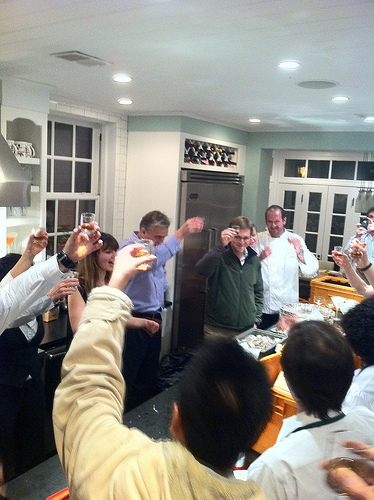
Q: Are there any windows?
A: Yes, there is a window.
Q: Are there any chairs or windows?
A: Yes, there is a window.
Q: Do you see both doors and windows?
A: Yes, there are both a window and a door.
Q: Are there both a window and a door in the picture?
A: Yes, there are both a window and a door.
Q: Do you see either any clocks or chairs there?
A: No, there are no chairs or clocks.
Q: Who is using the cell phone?
A: The man is using the cell phone.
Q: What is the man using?
A: The man is using a cell phone.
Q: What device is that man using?
A: The man is using a cellphone.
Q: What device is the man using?
A: The man is using a cellphone.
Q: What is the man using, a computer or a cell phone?
A: The man is using a cell phone.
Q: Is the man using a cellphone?
A: Yes, the man is using a cellphone.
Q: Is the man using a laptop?
A: No, the man is using a cellphone.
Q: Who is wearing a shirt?
A: The man is wearing a shirt.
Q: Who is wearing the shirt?
A: The man is wearing a shirt.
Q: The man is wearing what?
A: The man is wearing a shirt.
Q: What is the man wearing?
A: The man is wearing a shirt.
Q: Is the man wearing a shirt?
A: Yes, the man is wearing a shirt.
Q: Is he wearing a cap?
A: No, the man is wearing a shirt.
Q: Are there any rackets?
A: No, there are no rackets.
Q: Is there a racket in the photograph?
A: No, there are no rackets.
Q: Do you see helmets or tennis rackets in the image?
A: No, there are no tennis rackets or helmets.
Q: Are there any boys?
A: No, there are no boys.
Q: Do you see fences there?
A: No, there are no fences.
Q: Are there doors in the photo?
A: Yes, there is a door.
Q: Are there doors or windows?
A: Yes, there is a door.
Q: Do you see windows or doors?
A: Yes, there is a door.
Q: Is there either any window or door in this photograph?
A: Yes, there is a door.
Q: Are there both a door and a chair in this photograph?
A: No, there is a door but no chairs.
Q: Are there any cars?
A: No, there are no cars.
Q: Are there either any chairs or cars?
A: No, there are no cars or chairs.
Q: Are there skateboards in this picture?
A: No, there are no skateboards.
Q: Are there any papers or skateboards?
A: No, there are no skateboards or papers.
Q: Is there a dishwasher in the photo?
A: Yes, there is a dishwasher.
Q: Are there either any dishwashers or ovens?
A: Yes, there is a dishwasher.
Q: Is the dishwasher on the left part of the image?
A: Yes, the dishwasher is on the left of the image.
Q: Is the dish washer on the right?
A: No, the dish washer is on the left of the image.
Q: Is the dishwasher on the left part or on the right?
A: The dishwasher is on the left of the image.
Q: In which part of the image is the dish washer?
A: The dish washer is on the left of the image.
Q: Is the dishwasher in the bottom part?
A: Yes, the dishwasher is in the bottom of the image.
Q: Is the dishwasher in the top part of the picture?
A: No, the dishwasher is in the bottom of the image.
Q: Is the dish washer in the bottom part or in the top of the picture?
A: The dish washer is in the bottom of the image.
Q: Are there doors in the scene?
A: Yes, there is a door.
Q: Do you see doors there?
A: Yes, there is a door.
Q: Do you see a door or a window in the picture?
A: Yes, there is a door.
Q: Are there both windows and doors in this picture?
A: Yes, there are both a door and a window.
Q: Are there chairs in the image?
A: No, there are no chairs.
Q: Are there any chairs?
A: No, there are no chairs.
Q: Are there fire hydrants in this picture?
A: No, there are no fire hydrants.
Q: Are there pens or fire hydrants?
A: No, there are no fire hydrants or pens.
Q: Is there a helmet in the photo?
A: No, there are no helmets.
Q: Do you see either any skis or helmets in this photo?
A: No, there are no helmets or skis.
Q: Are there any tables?
A: Yes, there is a table.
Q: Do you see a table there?
A: Yes, there is a table.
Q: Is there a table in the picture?
A: Yes, there is a table.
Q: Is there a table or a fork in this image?
A: Yes, there is a table.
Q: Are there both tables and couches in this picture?
A: No, there is a table but no couches.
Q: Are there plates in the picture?
A: No, there are no plates.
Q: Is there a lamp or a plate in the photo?
A: No, there are no plates or lamps.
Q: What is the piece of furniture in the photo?
A: The piece of furniture is a table.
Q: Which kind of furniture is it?
A: The piece of furniture is a table.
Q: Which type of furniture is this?
A: This is a table.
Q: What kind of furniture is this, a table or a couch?
A: This is a table.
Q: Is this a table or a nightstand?
A: This is a table.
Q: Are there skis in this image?
A: No, there are no skis.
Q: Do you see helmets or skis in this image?
A: No, there are no skis or helmets.